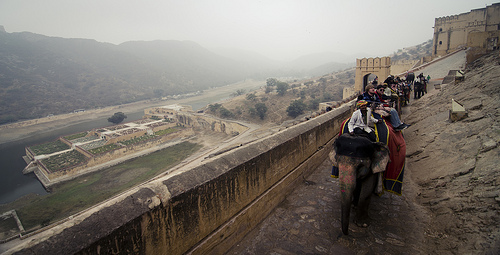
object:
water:
[0, 93, 230, 204]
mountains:
[0, 23, 273, 126]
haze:
[0, 0, 500, 94]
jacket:
[347, 108, 380, 134]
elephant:
[327, 132, 393, 237]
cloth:
[329, 112, 407, 196]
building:
[430, 2, 499, 56]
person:
[345, 100, 381, 144]